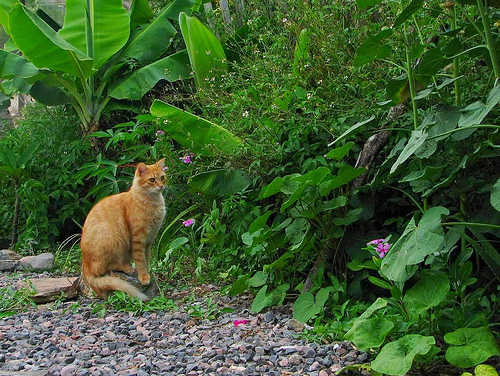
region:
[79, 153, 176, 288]
this is a cat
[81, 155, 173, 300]
the cat is motionless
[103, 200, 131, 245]
the fur is brown in color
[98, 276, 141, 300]
this is the tail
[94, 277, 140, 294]
the tail is long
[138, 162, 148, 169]
this is the ear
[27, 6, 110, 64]
the leaves are behind the cat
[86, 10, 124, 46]
the leaf is broad in size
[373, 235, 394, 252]
the flower is purple in color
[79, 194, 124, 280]
the cat is big in size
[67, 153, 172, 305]
an orange cat on rocks.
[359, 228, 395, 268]
a purple flower on a green plant.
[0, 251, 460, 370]
a road covered in rocks.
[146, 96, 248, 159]
a big leafy plant.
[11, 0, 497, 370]
a leafy green jungle.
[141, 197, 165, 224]
a cat's hairy chest.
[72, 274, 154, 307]
a tail on an orange cat.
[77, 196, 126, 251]
the back of an orange cat.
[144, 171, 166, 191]
a cat's little face.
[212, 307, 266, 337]
a flower on the ground.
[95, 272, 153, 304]
The tail of the cat.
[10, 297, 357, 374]
The pile of small rocks on the ground.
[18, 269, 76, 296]
The large brown rock behind the cat.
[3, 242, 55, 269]
The two gray rocks behind the cat.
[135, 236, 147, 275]
The cat's visible front leg.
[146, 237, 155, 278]
The cat's partially visible front leg.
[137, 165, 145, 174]
The left ear of the cat.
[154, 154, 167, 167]
The right ear of the cat.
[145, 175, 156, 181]
The left eye of the cat.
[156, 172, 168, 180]
The right eye of the cat.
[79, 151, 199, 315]
Orange cat sitting on the ground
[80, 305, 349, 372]
Rocks laying on ground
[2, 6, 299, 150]
Banana tree growing behind cat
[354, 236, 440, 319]
Purple flowers on plant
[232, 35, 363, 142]
Weeds growing between plants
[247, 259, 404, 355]
Green leaves on ground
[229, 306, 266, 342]
Purple flower petals in stone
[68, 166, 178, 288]
The cat has orange stripes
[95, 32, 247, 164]
Large leaves on plant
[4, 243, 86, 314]
Large boulders behind cat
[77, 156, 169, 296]
the cat is big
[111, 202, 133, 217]
the fur is brown in color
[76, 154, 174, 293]
the cat is standing on a rock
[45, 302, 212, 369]
these are some pebbles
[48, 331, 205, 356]
the pebbles are small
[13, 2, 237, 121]
these are some leaves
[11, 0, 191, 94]
the leaves are big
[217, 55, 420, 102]
the leaves are green in color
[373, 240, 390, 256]
the flower is pink in color